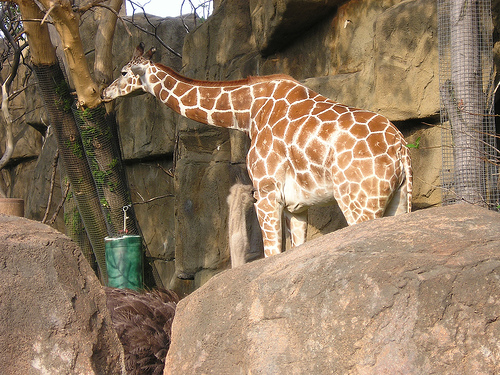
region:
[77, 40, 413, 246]
giraffe eating tan tree trunk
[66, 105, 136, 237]
wire mesh over trees and green leaves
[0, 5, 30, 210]
curved bare branch in planter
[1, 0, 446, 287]
giraffe standing by tan wall of rocks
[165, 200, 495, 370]
gray boulder with pinkish highlights on cracked surface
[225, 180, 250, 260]
upright curved log by giraffe's foot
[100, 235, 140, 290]
green container with design of a branch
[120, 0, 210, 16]
bright light from opening at top of wall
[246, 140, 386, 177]
white spots in middle of brown patches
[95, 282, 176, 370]
brown curved feathers between rocks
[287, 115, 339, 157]
pattern on side of giraffe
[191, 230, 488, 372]
large red boulder beside giraffe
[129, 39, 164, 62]
small horns on head of giraffee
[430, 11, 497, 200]
grey metal fencing around tree trunk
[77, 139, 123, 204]
tree with small green leaves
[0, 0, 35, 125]
tree branches with no leaves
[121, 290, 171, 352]
brown feathers on ostrich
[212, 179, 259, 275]
long neck of ostrich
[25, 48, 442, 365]
giraffe and ostrich side by side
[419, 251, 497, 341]
cracks in large red boulder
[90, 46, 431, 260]
a giraffe inside a pen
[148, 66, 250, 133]
long neck of giraffe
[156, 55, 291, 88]
mane of giraffe is brown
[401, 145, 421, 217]
the tail of giraffe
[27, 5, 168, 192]
giraffe is eating bark of tree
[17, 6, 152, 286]
trunk of tree in front a giraffe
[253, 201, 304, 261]
front feet of giraffe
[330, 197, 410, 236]
back feet of giraffe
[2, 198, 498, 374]
two big rocks in a pen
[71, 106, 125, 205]
moss on a tree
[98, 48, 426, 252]
a giraffe standing in a pen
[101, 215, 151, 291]
green bucket hanging from a tree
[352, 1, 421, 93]
brown rock wall of the pen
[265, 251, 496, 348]
a large brown boulder in the pen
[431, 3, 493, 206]
grey chain link fence wrapped around the tree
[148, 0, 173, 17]
cloudy grey skies over the pen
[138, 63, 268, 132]
long spotted neck of the giraffe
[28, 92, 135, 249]
green leaves growing inside the fence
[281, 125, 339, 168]
brown spots of the giraffe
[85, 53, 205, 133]
a giraffe eating leaves from a tree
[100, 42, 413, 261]
giraffe bends it's neck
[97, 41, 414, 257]
giraffe stands on four legs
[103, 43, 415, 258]
giraffe examines the tree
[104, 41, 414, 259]
giraffe is covered in spots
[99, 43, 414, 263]
giraffe is behind the rock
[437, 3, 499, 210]
tree is surrounded by wire mesh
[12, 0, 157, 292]
tree is behind rock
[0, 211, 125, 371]
rock is in front of tree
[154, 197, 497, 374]
rock is in front of giraffe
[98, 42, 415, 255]
giraffe is next to tree